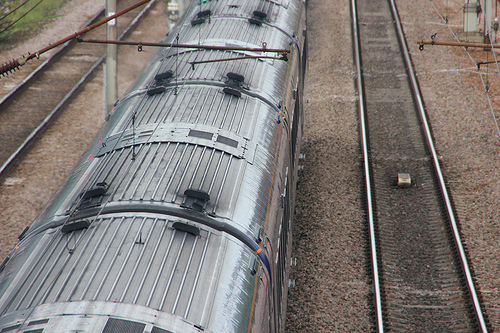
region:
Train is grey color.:
[67, 186, 254, 293]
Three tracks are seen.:
[22, 34, 452, 254]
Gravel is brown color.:
[308, 176, 358, 290]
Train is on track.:
[70, 81, 225, 229]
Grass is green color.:
[1, 0, 46, 30]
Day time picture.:
[40, 16, 480, 316]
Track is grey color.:
[341, 165, 466, 240]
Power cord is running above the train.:
[0, 5, 200, 116]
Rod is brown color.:
[13, 20, 285, 72]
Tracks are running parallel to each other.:
[21, 27, 497, 288]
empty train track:
[345, 2, 490, 332]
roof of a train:
[3, 1, 310, 331]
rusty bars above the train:
[2, 2, 297, 81]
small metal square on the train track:
[390, 167, 417, 192]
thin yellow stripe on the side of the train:
[231, 0, 299, 332]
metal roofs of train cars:
[5, 3, 322, 331]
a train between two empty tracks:
[6, 1, 496, 332]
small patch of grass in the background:
[1, 1, 63, 42]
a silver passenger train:
[6, 1, 321, 331]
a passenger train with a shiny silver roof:
[3, 1, 325, 331]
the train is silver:
[3, 0, 305, 330]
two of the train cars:
[19, 15, 304, 330]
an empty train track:
[349, 0, 489, 332]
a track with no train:
[1, 2, 154, 175]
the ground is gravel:
[285, 0, 375, 330]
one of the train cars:
[17, 82, 286, 330]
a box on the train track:
[393, 170, 413, 189]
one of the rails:
[349, 0, 389, 330]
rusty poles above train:
[3, 0, 291, 90]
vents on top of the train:
[96, 121, 260, 163]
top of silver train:
[6, 1, 337, 329]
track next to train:
[347, 123, 479, 293]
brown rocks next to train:
[301, 139, 356, 264]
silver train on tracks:
[68, 121, 303, 303]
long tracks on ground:
[321, 3, 452, 324]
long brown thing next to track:
[405, 31, 484, 66]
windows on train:
[266, 205, 298, 270]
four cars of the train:
[61, 6, 302, 320]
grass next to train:
[10, 2, 52, 38]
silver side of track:
[352, 114, 382, 174]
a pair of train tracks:
[345, 0, 495, 332]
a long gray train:
[0, 0, 315, 332]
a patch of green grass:
[0, 0, 65, 51]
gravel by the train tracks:
[0, 0, 185, 265]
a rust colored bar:
[0, 0, 150, 87]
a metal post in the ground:
[394, 161, 420, 192]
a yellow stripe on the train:
[254, 122, 282, 250]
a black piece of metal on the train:
[181, 184, 221, 205]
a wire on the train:
[123, 106, 145, 168]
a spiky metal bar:
[0, 49, 31, 87]